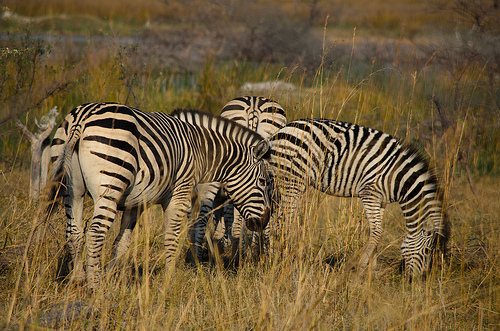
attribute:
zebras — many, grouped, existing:
[43, 92, 458, 291]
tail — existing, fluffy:
[39, 124, 83, 225]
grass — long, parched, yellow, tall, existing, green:
[5, 0, 498, 330]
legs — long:
[60, 184, 118, 295]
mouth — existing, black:
[247, 218, 267, 233]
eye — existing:
[258, 175, 267, 187]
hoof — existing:
[71, 271, 88, 287]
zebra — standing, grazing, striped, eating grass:
[41, 101, 274, 293]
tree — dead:
[402, 2, 500, 151]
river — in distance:
[4, 30, 138, 58]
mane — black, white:
[170, 106, 268, 158]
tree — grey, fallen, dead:
[236, 78, 294, 90]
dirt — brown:
[316, 25, 399, 46]